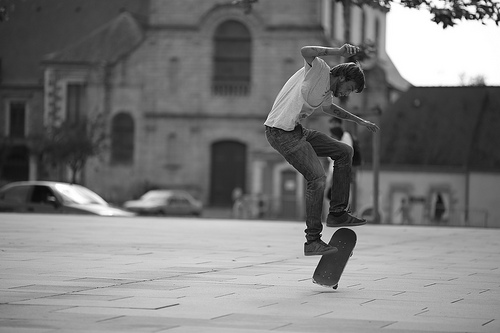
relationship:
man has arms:
[266, 45, 379, 255] [301, 36, 385, 128]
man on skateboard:
[263, 43, 381, 256] [314, 231, 357, 284]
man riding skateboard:
[263, 43, 381, 256] [302, 228, 359, 292]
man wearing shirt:
[263, 43, 381, 256] [261, 51, 338, 138]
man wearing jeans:
[263, 43, 381, 256] [259, 117, 355, 241]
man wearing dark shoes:
[263, 43, 381, 256] [296, 206, 368, 255]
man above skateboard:
[263, 43, 381, 256] [310, 224, 363, 293]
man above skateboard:
[266, 45, 379, 255] [311, 227, 357, 288]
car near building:
[121, 177, 212, 224] [0, 2, 497, 231]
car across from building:
[1, 180, 138, 217] [0, 2, 497, 231]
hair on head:
[330, 60, 365, 94] [330, 60, 365, 98]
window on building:
[204, 20, 259, 102] [151, 3, 276, 235]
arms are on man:
[299, 42, 379, 132] [263, 43, 381, 256]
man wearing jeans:
[263, 43, 381, 256] [263, 121, 353, 238]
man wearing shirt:
[263, 43, 381, 256] [245, 21, 404, 198]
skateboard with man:
[312, 228, 354, 289] [263, 43, 381, 256]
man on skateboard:
[263, 43, 381, 256] [312, 228, 354, 289]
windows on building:
[0, 3, 462, 223] [0, 2, 497, 231]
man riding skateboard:
[263, 43, 381, 256] [312, 225, 359, 290]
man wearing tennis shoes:
[263, 43, 381, 256] [326, 211, 368, 228]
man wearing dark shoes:
[263, 43, 381, 256] [304, 240, 338, 256]